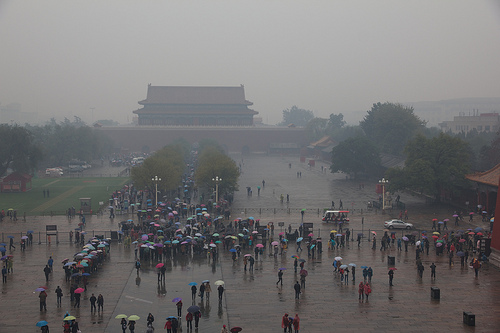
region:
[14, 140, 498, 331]
Crowd of people in the rain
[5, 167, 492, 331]
A crowd of people in the rain holding umbrellas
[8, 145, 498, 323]
Tourists in an Asian country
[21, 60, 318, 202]
Asian-style building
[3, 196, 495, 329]
people holding umbrellas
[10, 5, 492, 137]
gloomy, rainy sky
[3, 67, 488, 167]
an Asian-style building surrounded by trees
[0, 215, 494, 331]
people standing in rain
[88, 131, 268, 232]
tree-lined path in front of a large buildling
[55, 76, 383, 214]
An Asian-style building behind a wall.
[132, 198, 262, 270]
A large group of people with umbrellas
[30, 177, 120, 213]
A large green lawn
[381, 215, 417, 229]
Silver compact car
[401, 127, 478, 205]
Dark green tree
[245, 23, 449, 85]
Cloudy sky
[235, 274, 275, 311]
A patch of wet ground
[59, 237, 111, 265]
A line of people holding umbrellas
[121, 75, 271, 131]
Building that resembles a temple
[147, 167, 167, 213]
Tall lamp post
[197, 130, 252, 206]
Long line of light green trees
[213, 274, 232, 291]
person with white umbrella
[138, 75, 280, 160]
large chinese building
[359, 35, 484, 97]
over cast day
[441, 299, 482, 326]
boxlike object on ground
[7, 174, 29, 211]
red building on middle left of picture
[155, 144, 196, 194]
green trees with leaves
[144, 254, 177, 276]
people with red umbrellas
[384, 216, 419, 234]
white parked car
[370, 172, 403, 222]
light fixture on right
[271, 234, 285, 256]
pink umbrella protecting from rain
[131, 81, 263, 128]
a tall fancy building in the background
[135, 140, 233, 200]
two rows of trees by the plaza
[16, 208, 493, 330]
a crowd of people holding umbrellas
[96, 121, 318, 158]
a fence in front of the building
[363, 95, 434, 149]
a tall leafy tree off to the side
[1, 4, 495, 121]
the grey cloudy sky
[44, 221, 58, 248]
a tall chair next to the fence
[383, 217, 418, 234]
a small car on the road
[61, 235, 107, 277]
people waiting in line for something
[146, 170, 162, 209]
a street light next to the fence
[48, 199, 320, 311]
Many people with umbrellas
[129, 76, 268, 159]
Large building in the fog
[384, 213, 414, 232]
The car is white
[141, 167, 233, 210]
Tall white light poles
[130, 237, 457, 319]
The ground is brown brick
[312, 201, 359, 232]
Red and white vehicle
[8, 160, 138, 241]
The green field is square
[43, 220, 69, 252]
The sign is brown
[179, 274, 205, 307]
Person with a blue umbrella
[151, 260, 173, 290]
Person holding a red umbrella